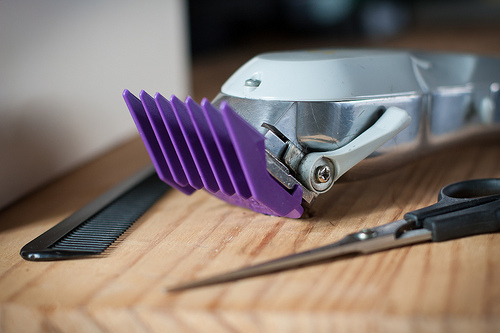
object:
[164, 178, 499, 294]
scissors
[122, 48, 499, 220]
razor machine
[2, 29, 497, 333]
table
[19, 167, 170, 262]
comb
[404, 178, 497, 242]
handle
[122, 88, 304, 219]
blade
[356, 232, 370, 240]
screw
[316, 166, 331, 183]
screw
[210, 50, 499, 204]
section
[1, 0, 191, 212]
wall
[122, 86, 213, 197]
part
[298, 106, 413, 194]
level